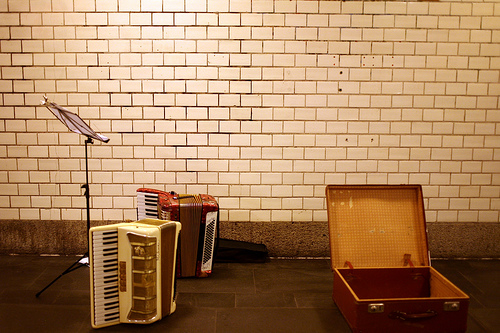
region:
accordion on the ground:
[85, 219, 166, 323]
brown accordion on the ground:
[153, 178, 219, 270]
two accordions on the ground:
[78, 180, 215, 320]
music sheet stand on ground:
[58, 97, 101, 141]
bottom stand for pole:
[35, 250, 92, 308]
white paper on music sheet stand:
[52, 94, 101, 152]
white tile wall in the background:
[98, 7, 347, 149]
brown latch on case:
[398, 250, 422, 270]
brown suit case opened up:
[323, 180, 473, 325]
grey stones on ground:
[211, 276, 322, 328]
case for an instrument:
[310, 177, 470, 326]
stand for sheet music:
[26, 86, 126, 310]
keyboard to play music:
[74, 212, 179, 324]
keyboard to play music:
[117, 178, 219, 276]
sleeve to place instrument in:
[208, 229, 272, 272]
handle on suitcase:
[397, 301, 434, 323]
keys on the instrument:
[91, 230, 121, 322]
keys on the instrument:
[131, 193, 159, 222]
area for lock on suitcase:
[360, 301, 382, 318]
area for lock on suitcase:
[443, 301, 463, 311]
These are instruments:
[30, 90, 254, 330]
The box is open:
[268, 176, 485, 331]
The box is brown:
[281, 170, 488, 332]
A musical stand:
[12, 90, 133, 324]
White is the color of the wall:
[152, 30, 390, 137]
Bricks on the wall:
[157, 20, 307, 153]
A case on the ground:
[120, 205, 290, 272]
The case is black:
[185, 217, 271, 282]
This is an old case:
[327, 183, 434, 280]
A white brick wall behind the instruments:
[144, 43, 291, 163]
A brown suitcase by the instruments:
[318, 180, 470, 329]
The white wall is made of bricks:
[0, 0, 499, 222]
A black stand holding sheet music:
[32, 93, 133, 297]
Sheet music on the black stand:
[50, 100, 117, 142]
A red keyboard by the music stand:
[137, 183, 222, 279]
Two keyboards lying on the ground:
[81, 184, 241, 323]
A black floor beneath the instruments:
[208, 283, 310, 330]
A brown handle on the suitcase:
[398, 307, 447, 322]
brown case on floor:
[313, 161, 456, 318]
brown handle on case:
[405, 306, 449, 329]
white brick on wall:
[303, 27, 409, 137]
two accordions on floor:
[109, 160, 230, 323]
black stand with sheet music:
[30, 91, 97, 295]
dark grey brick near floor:
[233, 219, 305, 266]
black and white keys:
[95, 228, 127, 330]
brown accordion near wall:
[135, 176, 226, 272]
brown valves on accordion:
[173, 191, 197, 276]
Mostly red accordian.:
[133, 186, 220, 276]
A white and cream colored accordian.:
[87, 216, 179, 329]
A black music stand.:
[35, 97, 109, 295]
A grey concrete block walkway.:
[1, 253, 499, 331]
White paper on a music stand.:
[45, 102, 103, 140]